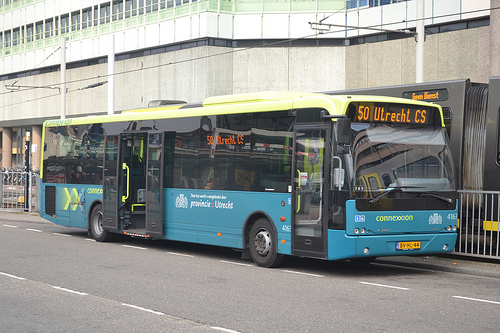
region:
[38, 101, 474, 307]
this is a bus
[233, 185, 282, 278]
this is a wheel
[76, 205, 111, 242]
this is a wheel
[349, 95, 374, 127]
this is a a number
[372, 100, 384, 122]
this is a letter on the bus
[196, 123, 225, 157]
this is a letter on the bus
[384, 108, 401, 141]
this is a letter on the bus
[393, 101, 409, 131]
this is a letter on the bus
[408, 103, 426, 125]
this is a letter on the bus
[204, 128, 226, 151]
this is a letter on the bus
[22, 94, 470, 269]
Umbrellas on top of sugarcane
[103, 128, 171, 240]
Doors ajar on a bus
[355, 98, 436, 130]
electric sign on a bus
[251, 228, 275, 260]
silver rims on a bus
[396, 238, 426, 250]
license plate on a bus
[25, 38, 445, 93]
electric wires above the bus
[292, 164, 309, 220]
stepping handle on the bus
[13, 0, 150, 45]
row of windows on a building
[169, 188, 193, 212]
logo on a bus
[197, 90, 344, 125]
yellow roof on a bus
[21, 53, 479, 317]
A bus in Holland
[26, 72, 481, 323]
A bus heading for Utrecht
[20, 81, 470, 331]
A bus with the rear doors open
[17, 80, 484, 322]
A Dutch bus going to Utrecht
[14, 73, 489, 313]
a bus in the Netherlands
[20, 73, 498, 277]
a bus blue on the bottom and yellow on the top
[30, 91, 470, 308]
Number 50 bus going to Utrecht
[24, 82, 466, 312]
number 50 bus going to Utrecht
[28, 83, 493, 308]
The Utrecht bus with the back door open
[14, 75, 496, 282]
a Dutch bus with the back door opened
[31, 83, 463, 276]
bus on the street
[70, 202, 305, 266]
wheels on the bus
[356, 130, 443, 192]
front window on the bus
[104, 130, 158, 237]
open door on bus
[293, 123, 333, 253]
door on the bus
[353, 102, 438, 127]
bus route and number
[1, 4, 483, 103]
concrete building behind bus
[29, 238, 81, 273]
lane for vehicles to travel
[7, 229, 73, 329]
street for vehicles to travel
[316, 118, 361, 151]
mirror on the bus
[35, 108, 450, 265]
blue and yellow bus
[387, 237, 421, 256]
yellow and black license plate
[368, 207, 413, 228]
yellow logo on bus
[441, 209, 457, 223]
white number on bus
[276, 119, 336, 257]
black frame around door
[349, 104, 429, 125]
orange LCD with destination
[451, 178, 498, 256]
grey rail behind bus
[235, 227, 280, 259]
black tires on bus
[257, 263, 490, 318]
white lines on road